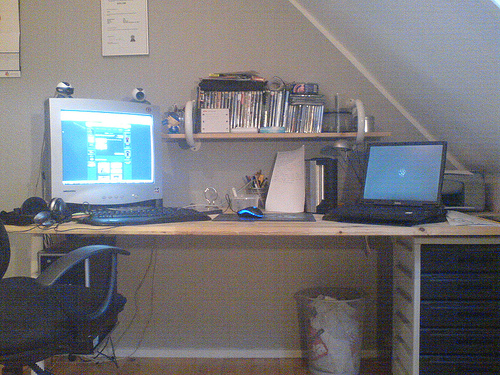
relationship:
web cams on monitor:
[58, 83, 154, 102] [46, 101, 166, 204]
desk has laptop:
[0, 199, 496, 367] [321, 138, 448, 222]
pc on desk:
[47, 95, 213, 226] [0, 199, 496, 367]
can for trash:
[293, 283, 370, 375] [309, 307, 351, 365]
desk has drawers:
[0, 199, 496, 367] [392, 224, 498, 372]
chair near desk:
[3, 217, 127, 373] [0, 199, 496, 367]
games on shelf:
[194, 91, 323, 132] [169, 86, 390, 143]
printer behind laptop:
[443, 169, 490, 211] [321, 138, 448, 222]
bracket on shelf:
[184, 96, 200, 157] [169, 86, 390, 143]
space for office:
[25, 32, 486, 361] [9, 17, 499, 372]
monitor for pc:
[46, 101, 166, 204] [47, 95, 213, 226]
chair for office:
[3, 217, 127, 373] [9, 17, 499, 372]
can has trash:
[293, 283, 370, 375] [309, 307, 351, 365]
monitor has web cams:
[46, 101, 166, 204] [58, 83, 154, 102]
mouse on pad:
[239, 204, 264, 217] [213, 208, 312, 223]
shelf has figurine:
[169, 86, 390, 143] [167, 102, 180, 134]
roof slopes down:
[294, 0, 499, 233] [299, 7, 498, 106]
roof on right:
[294, 0, 499, 233] [286, 1, 499, 368]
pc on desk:
[49, 73, 450, 232] [0, 199, 496, 367]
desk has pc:
[0, 199, 496, 367] [49, 73, 450, 232]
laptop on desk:
[321, 138, 448, 222] [0, 199, 496, 367]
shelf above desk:
[169, 86, 390, 143] [0, 199, 496, 367]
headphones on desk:
[26, 197, 71, 232] [0, 199, 496, 367]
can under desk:
[293, 283, 370, 375] [0, 199, 496, 367]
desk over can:
[0, 199, 496, 367] [293, 283, 370, 375]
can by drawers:
[293, 283, 370, 375] [392, 224, 498, 372]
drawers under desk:
[392, 224, 498, 372] [0, 199, 496, 367]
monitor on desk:
[46, 101, 166, 204] [0, 199, 496, 367]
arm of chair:
[35, 242, 127, 317] [3, 217, 127, 373]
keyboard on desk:
[77, 203, 213, 227] [0, 199, 496, 367]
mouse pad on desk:
[213, 208, 312, 223] [0, 199, 496, 367]